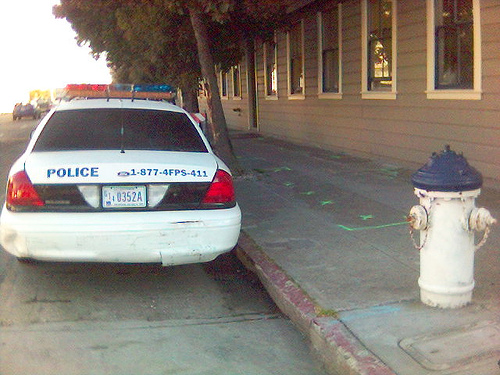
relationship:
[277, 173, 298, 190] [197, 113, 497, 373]
marks on sidewalk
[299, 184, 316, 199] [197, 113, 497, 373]
marks on sidewalk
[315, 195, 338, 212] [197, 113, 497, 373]
marks on sidewalk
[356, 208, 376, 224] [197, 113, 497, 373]
marks on sidewalk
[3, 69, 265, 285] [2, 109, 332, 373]
car parked on street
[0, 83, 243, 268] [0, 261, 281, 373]
car parked on street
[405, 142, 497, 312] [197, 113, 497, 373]
hydrant on sidewalk